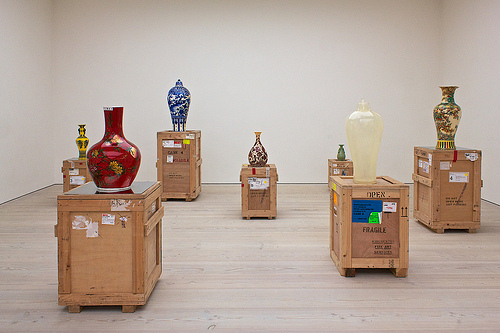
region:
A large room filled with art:
[17, 17, 494, 322]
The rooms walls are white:
[20, 18, 472, 200]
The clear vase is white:
[336, 87, 384, 182]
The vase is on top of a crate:
[42, 163, 176, 315]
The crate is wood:
[44, 181, 176, 311]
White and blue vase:
[162, 79, 197, 127]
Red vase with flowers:
[80, 95, 147, 188]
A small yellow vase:
[68, 115, 90, 153]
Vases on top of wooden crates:
[46, 51, 484, 300]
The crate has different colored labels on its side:
[328, 165, 418, 267]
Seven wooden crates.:
[23, 26, 495, 328]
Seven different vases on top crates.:
[35, 12, 488, 317]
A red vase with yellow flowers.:
[76, 89, 161, 201]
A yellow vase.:
[68, 112, 93, 159]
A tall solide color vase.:
[341, 79, 393, 194]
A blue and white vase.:
[159, 70, 198, 140]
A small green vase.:
[331, 135, 356, 172]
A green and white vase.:
[421, 70, 473, 150]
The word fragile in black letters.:
[357, 220, 392, 237]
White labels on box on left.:
[63, 197, 135, 242]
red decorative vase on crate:
[79, 89, 166, 296]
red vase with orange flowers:
[96, 99, 148, 189]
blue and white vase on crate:
[153, 74, 210, 194]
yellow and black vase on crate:
[56, 108, 91, 189]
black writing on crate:
[348, 223, 418, 280]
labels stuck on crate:
[67, 208, 167, 255]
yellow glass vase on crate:
[330, 86, 407, 227]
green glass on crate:
[322, 137, 361, 177]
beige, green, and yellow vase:
[406, 70, 492, 200]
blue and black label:
[349, 193, 382, 213]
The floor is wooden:
[219, 259, 242, 324]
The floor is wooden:
[221, 223, 301, 324]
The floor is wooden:
[261, 255, 293, 328]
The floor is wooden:
[247, 303, 264, 330]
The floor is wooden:
[234, 266, 278, 331]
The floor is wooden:
[275, 296, 290, 321]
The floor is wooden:
[262, 303, 278, 326]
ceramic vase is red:
[96, 100, 146, 196]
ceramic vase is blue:
[163, 81, 190, 128]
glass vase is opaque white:
[345, 96, 380, 180]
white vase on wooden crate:
[327, 166, 412, 278]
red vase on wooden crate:
[42, 168, 162, 308]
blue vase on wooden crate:
[151, 134, 201, 199]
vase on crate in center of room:
[225, 126, 287, 225]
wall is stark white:
[58, 0, 443, 175]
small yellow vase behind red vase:
[76, 122, 88, 155]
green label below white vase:
[368, 210, 384, 226]